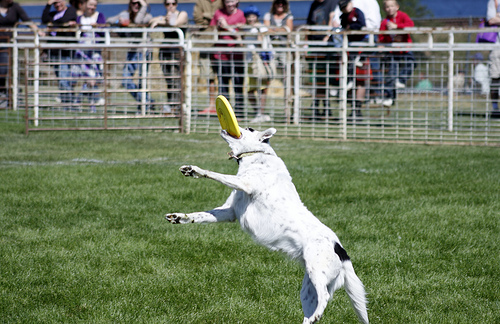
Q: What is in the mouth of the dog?
A: A frisbee.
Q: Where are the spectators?
A: In the distance.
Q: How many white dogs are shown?
A: 1.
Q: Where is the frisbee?
A: Dog's mouth.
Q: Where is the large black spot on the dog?
A: Base of tail.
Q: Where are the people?
A: Behind the fence.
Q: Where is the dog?
A: In grass field.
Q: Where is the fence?
A: Background.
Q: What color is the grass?
A: Green.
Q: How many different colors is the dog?
A: 2.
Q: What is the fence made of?
A: Metal.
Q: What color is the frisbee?
A: Yellow.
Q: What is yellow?
A: Frisbee.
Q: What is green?
A: Grass.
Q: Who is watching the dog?
A: Spectators.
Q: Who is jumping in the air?
A: A dog.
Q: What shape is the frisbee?
A: Round.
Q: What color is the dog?
A: White.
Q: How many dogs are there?
A: One.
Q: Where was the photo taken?
A: Day time.